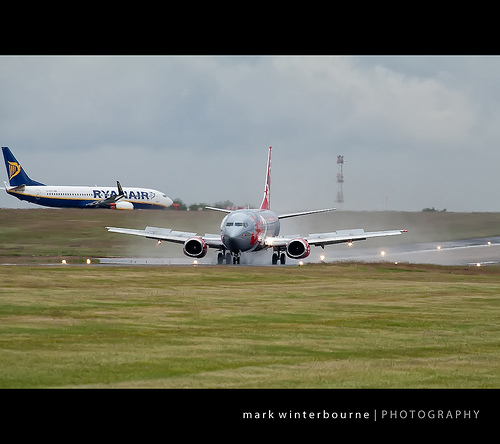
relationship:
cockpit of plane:
[222, 221, 256, 227] [102, 140, 411, 269]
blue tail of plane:
[1, 139, 41, 185] [0, 142, 180, 227]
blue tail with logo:
[1, 139, 41, 185] [7, 161, 22, 180]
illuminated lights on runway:
[53, 250, 93, 265] [84, 224, 475, 274]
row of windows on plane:
[45, 190, 95, 199] [7, 147, 177, 219]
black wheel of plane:
[272, 253, 286, 263] [102, 140, 411, 269]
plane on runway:
[0, 141, 194, 220] [241, 240, 484, 276]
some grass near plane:
[4, 260, 500, 385] [102, 140, 411, 269]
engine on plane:
[275, 234, 314, 265] [93, 138, 421, 275]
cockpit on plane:
[222, 221, 257, 233] [102, 140, 411, 269]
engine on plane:
[178, 231, 212, 262] [102, 140, 411, 269]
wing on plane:
[271, 227, 410, 246] [102, 140, 411, 269]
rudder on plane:
[143, 221, 172, 237] [253, 140, 283, 213]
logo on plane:
[5, 155, 24, 185] [0, 142, 180, 214]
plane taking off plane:
[0, 141, 194, 220] [0, 141, 194, 220]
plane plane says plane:
[4, 141, 193, 220] [110, 147, 409, 282]